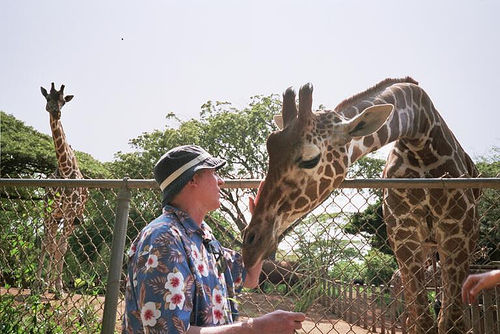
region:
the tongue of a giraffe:
[242, 260, 262, 287]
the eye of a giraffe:
[295, 150, 320, 170]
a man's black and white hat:
[145, 145, 220, 205]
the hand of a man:
[241, 296, 301, 328]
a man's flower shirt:
[120, 201, 225, 328]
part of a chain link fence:
[0, 160, 497, 330]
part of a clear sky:
[0, 0, 496, 60]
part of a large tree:
[115, 87, 366, 278]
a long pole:
[359, 280, 376, 329]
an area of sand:
[301, 303, 358, 331]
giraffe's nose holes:
[242, 227, 259, 244]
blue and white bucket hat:
[152, 144, 224, 204]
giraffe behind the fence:
[33, 83, 84, 295]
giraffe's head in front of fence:
[241, 85, 393, 267]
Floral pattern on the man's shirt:
[123, 215, 242, 332]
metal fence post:
[100, 178, 131, 330]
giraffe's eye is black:
[297, 151, 322, 168]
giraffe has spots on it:
[242, 77, 485, 332]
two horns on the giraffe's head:
[282, 83, 312, 118]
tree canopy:
[0, 111, 100, 178]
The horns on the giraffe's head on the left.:
[50, 80, 65, 91]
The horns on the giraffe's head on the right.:
[275, 86, 315, 112]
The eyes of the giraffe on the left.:
[45, 94, 66, 104]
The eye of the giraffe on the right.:
[294, 150, 325, 172]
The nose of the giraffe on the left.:
[47, 105, 62, 117]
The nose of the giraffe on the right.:
[237, 226, 278, 264]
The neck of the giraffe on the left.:
[47, 114, 72, 173]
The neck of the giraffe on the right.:
[342, 76, 429, 152]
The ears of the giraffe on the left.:
[36, 87, 74, 98]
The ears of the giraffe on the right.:
[270, 106, 396, 133]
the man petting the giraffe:
[121, 143, 306, 333]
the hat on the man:
[152, 143, 225, 208]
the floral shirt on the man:
[122, 204, 246, 332]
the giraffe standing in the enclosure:
[39, 81, 89, 297]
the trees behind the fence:
[0, 90, 499, 332]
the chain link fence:
[1, 169, 498, 332]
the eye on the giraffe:
[296, 153, 323, 170]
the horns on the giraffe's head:
[280, 83, 313, 125]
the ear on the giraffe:
[346, 103, 393, 138]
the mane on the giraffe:
[333, 76, 418, 111]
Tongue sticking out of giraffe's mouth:
[240, 239, 266, 287]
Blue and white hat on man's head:
[153, 143, 228, 205]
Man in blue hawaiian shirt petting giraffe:
[125, 77, 479, 332]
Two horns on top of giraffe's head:
[280, 82, 316, 119]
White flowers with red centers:
[165, 271, 185, 310]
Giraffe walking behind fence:
[35, 78, 90, 297]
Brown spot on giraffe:
[427, 125, 454, 155]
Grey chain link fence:
[1, 158, 498, 332]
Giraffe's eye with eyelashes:
[296, 146, 323, 173]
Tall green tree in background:
[103, 90, 339, 292]